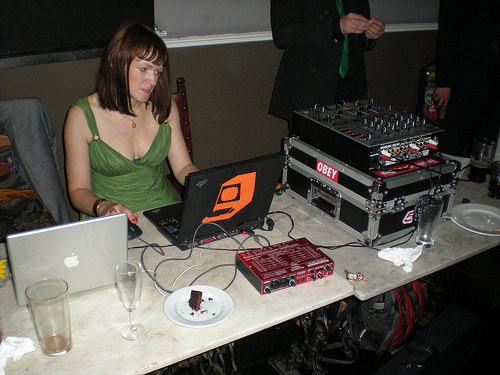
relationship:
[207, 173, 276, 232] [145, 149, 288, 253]
orange design on cover of laptop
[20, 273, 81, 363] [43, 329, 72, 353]
clear glass has liquid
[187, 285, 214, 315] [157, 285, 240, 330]
cake on top of white plate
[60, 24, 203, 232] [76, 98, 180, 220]
woman wearing dress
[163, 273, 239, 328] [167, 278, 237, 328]
white plate on top of table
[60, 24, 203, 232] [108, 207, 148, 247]
woman uses black mouse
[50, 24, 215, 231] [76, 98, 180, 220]
woman uses dress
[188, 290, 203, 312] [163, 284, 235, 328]
cake on white plate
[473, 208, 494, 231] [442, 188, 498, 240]
crumbs on plate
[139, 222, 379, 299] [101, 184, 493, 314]
multiple wires under table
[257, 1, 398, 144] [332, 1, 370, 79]
man wears wearing a green tie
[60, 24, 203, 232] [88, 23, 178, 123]
woman has hair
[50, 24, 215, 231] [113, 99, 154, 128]
woman wears necklace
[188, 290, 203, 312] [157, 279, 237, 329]
cake on plate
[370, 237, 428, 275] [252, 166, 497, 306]
napkin on table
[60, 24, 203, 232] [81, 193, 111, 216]
woman wearing a bracelet